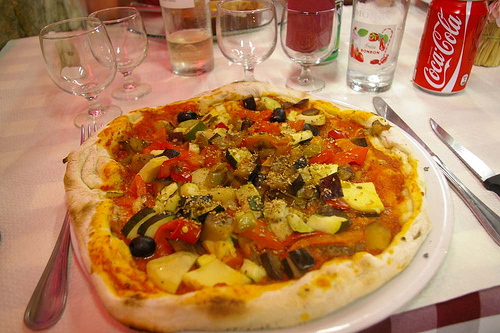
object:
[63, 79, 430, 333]
pizza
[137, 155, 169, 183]
vegetable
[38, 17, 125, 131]
glass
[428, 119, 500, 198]
knife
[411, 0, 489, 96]
coca cola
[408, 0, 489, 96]
can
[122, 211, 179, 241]
zucchini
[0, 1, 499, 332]
table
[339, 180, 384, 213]
pineapple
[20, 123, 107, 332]
fork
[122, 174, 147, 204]
pepper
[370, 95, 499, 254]
knife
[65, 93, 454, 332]
plate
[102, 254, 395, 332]
crust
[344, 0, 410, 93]
bottle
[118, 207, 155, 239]
veggie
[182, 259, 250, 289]
squash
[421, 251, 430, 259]
spot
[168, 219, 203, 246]
pepper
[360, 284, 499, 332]
tablecloth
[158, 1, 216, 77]
glass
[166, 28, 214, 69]
tea